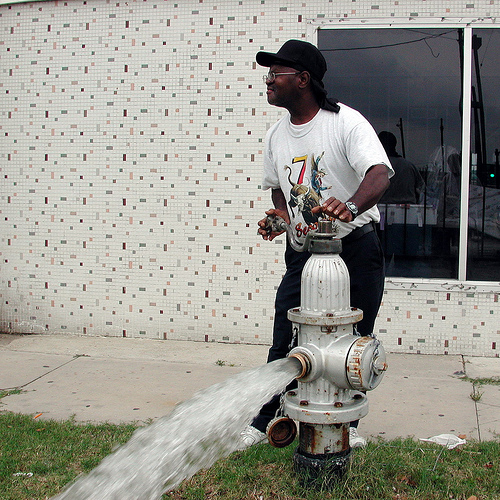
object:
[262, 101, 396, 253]
shirt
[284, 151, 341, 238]
graphic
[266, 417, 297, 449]
cap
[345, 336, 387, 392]
cap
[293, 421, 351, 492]
base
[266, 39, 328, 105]
head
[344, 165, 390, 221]
arm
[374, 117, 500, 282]
reflection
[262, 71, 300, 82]
eyeglasses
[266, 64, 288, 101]
face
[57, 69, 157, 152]
tiles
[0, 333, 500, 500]
ground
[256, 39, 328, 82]
cap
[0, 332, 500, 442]
sidewalk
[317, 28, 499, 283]
window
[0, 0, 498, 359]
building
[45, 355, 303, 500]
stream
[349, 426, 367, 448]
shoe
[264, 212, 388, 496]
fire hydrant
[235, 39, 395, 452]
man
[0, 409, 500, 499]
grass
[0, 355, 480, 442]
floor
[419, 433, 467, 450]
garbage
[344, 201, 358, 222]
watch